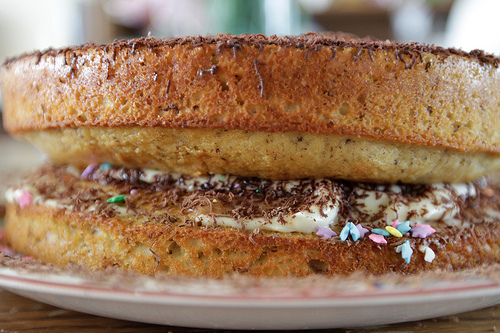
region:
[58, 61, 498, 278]
a sandwich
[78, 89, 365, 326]
a sandwich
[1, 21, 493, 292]
a two layered cake with whipped cream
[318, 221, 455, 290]
pastel star shaped sprinkles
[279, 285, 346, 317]
a red line along the edge of a white plate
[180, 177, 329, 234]
chocolate shavings on cream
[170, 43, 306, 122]
chocolate shavings on toasted cake crust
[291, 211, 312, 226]
white frosting between two sheets of cake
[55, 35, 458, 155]
a top layer of vanilla cake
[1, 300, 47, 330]
a dark brown wooden table top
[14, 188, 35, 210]
a rogue pink star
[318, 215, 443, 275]
purple pink and blue sprinkles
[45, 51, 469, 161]
brown and toasted bread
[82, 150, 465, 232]
white frosting between layers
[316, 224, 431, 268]
small and colorful sprinkles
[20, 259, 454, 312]
white plate below pastry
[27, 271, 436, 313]
red stripe on plate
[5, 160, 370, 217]
chocolate flakes on pastry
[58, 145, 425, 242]
white filling in center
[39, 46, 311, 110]
chocolate flakes on top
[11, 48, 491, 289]
brown pastry on plate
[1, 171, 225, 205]
icing with colored sprinkles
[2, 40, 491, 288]
Cake sitting on a plate.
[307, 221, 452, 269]
Star sprinkles on side of cake.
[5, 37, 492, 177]
Top layer on a cake.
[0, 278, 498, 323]
A red and white plate.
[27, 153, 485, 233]
Filling between cake layers.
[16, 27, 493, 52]
Chocolate shavings on cake.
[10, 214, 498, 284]
Bottom layer on a cake.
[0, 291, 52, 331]
A wooden table under plate.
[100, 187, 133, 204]
A green star sprinkle.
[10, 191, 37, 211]
1 pink star sprinkle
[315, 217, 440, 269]
Sprinkles in the food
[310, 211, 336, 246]
A puple star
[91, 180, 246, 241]
Flakes on the food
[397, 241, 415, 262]
the spinkle is blue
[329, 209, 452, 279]
The star sprinkles are colorful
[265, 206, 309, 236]
White on the toast.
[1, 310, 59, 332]
A wooden table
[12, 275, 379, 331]
The white plate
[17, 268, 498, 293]
Red trim on the white palte.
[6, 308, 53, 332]
dark lines in the wood table